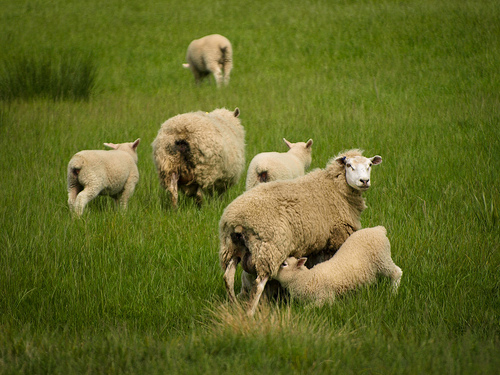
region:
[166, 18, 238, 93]
sheep walking on grass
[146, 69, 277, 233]
sheep walking on grass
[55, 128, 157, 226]
sheep walking on grass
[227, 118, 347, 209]
sheep walking on grass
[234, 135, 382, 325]
sheep walking on grass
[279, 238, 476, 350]
sheep walking on grass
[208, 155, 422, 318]
sheep drinking from sheep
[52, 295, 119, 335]
area of green grass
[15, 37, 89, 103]
area of green grass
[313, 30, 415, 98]
area of green grass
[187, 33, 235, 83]
the sheep is grazing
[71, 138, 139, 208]
the sheep is walking away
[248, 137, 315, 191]
the sheep is walking away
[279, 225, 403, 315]
the baby sheep is suckling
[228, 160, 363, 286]
the sheep is full of wool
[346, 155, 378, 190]
the sheep's face is white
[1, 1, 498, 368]
the grass is filled with grass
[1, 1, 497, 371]
the grass is green in color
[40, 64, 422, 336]
There are animals in the shot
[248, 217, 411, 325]
This is a baby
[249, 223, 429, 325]
The baby is eating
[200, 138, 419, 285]
This is a female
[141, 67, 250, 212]
The sheep's fur is white and fluffy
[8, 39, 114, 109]
This is a patch of grass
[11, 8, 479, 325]
The time of day is daytime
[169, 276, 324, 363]
This is brown grass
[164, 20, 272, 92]
A lone animal in the back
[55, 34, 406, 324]
A herd of six sheep.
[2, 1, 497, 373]
The group of sheep are in a grassy field.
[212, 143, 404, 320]
This sheep is nursing its young.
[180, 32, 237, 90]
This sheep is away from the group.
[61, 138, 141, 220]
This sheep is following another.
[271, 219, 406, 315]
This sheep is nursing from its mother.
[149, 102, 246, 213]
This is a fluffy sheep.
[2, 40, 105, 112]
A patch of long grass in the distance.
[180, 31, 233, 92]
The sheep is eating the grass.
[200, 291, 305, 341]
A small patch of yellowed grass.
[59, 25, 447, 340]
sheeps walking in the grass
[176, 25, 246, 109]
a sheep grazing in the pasture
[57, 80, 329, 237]
a mother sheep with her children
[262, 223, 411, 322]
a baby sheep sucking milk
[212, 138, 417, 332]
a mother sheep with a baby sheep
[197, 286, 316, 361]
a yellow patch of grass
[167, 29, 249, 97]
a sheep eating grass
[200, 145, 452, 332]
a baby sheep under a grown sheep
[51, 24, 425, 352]
seven sheeps standing in the grass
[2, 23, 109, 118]
a patch of tall green grass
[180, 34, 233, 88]
Tan sheep grazing with tiny tail.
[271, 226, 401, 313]
Lamb trying to nurse.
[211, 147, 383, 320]
Sheep with head turned around.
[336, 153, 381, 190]
White head on a mommy sheep.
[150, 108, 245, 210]
Largest sheep walking away.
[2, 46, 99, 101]
A tall area of darker green grass.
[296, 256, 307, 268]
Lamb ear on a baby trying to nurse.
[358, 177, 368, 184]
Nose on a sheep whos head is turned around.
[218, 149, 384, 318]
A Mommy sheep with baby under her.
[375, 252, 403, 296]
Back leg of a lamb trying to nurse.